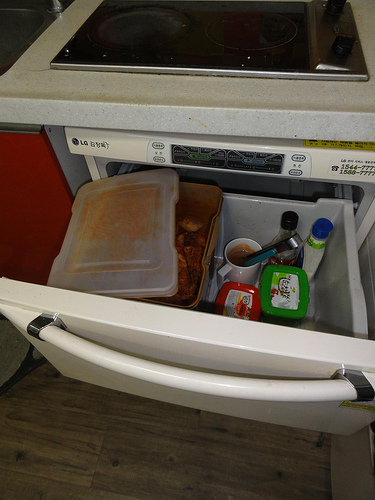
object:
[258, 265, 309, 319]
container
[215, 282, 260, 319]
top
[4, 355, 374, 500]
floor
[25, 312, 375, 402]
handle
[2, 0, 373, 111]
top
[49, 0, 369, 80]
cooktop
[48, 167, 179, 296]
top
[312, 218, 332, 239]
cap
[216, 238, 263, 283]
mug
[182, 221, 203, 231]
meat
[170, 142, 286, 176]
panel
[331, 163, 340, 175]
symbol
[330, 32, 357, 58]
knob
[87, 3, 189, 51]
burner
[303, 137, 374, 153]
sticker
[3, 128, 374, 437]
fridge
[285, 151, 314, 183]
buttons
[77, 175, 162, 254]
sauce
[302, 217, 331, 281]
bottle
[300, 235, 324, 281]
dressing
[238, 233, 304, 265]
tongs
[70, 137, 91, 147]
lg